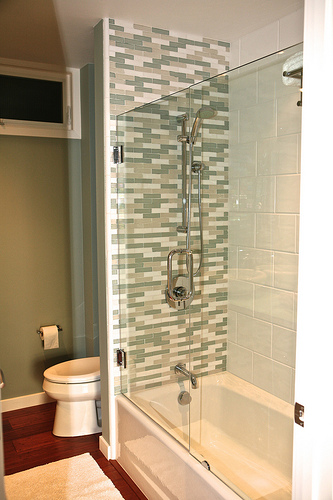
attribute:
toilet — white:
[42, 356, 102, 440]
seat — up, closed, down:
[43, 357, 102, 385]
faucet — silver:
[173, 362, 198, 392]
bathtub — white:
[118, 369, 293, 499]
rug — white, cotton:
[2, 452, 124, 500]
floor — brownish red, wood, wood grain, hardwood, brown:
[1, 401, 147, 499]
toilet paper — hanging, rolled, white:
[40, 325, 61, 351]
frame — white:
[1, 57, 83, 141]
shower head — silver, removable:
[195, 105, 219, 122]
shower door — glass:
[116, 42, 303, 499]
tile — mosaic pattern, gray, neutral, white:
[104, 18, 231, 392]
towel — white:
[281, 51, 303, 85]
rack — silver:
[281, 66, 304, 108]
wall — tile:
[91, 18, 226, 394]